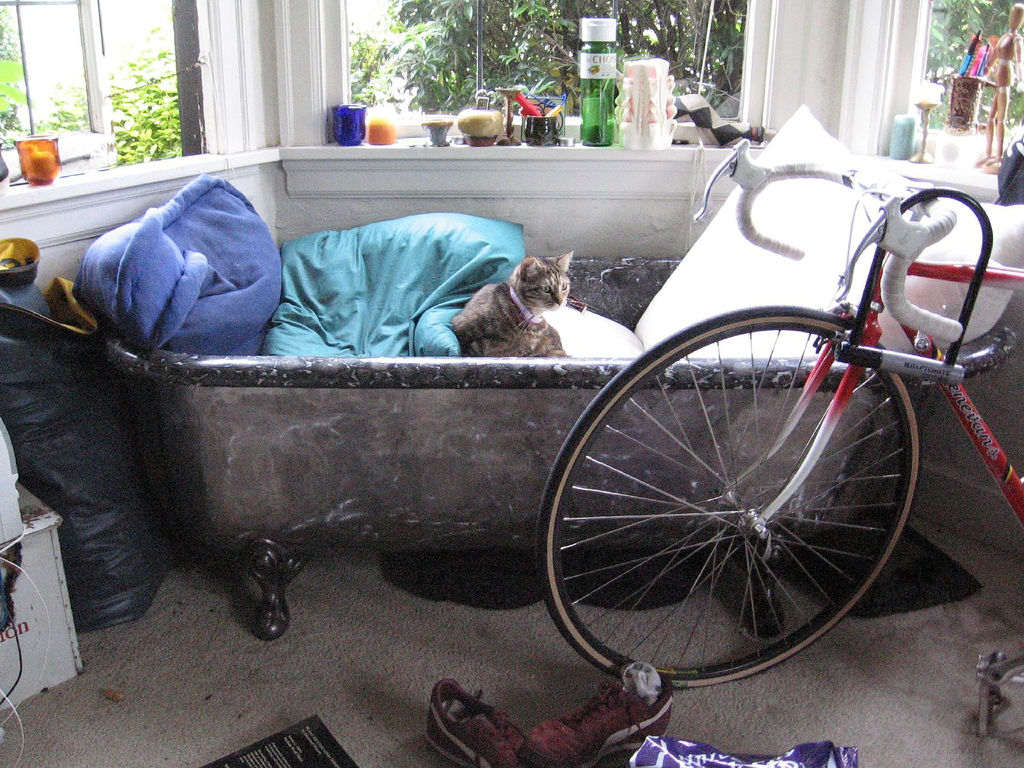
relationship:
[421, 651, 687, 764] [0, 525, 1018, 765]
shoes on ground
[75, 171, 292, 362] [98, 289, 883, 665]
pillow in claw tub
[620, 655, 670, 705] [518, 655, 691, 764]
sock in shoe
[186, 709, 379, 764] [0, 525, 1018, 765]
book on ground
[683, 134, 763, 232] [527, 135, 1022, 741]
brakes on bike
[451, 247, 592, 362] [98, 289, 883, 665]
cat laying in claw tub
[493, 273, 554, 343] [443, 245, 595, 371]
collar on cat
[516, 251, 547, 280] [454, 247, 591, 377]
ear on cat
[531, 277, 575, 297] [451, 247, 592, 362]
eyes of cat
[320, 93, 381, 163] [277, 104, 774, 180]
object on windowsill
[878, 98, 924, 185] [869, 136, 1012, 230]
object on windowsill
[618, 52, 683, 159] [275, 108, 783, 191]
object on windowsill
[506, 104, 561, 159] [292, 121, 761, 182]
object on windowsill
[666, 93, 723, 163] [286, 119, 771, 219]
object on windowsill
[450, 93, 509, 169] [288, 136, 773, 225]
object on windowsill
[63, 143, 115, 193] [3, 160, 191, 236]
object on windowsill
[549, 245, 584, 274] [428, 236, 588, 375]
ear of cat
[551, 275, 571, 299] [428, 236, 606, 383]
eye of cat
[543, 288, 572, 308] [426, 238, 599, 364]
nose of cat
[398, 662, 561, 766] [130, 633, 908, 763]
shoe on floor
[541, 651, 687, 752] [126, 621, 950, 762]
shoes on floor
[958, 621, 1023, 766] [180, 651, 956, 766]
shoe on floor